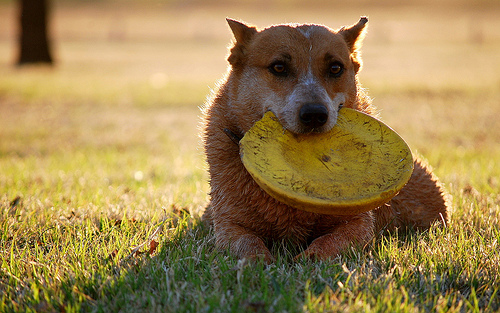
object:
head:
[225, 14, 370, 136]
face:
[252, 26, 356, 130]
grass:
[1, 0, 499, 312]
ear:
[339, 16, 373, 64]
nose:
[300, 99, 330, 128]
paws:
[291, 249, 342, 264]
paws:
[239, 251, 278, 269]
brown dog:
[207, 15, 451, 261]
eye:
[265, 56, 291, 76]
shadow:
[155, 263, 255, 293]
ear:
[226, 17, 256, 47]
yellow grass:
[13, 104, 123, 228]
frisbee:
[238, 107, 416, 215]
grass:
[27, 197, 170, 262]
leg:
[211, 209, 276, 267]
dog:
[200, 16, 449, 265]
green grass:
[4, 144, 194, 242]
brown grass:
[0, 61, 206, 151]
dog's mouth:
[274, 98, 343, 138]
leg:
[292, 209, 374, 263]